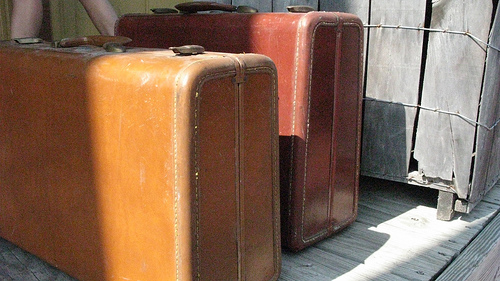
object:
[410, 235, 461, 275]
nails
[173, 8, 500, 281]
stitched seams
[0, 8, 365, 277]
suitcase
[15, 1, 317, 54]
apphendage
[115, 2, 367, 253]
suit case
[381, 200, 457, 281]
ground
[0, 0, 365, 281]
luggage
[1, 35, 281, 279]
brown suitcase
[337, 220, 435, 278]
wood decking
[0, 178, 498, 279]
floor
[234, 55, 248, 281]
seam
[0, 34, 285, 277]
briefcase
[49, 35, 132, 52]
handle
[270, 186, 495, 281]
slats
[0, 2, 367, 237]
box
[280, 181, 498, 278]
decking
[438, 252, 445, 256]
screws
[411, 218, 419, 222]
screws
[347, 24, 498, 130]
wire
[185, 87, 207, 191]
appointments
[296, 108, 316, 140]
appointments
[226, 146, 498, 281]
stand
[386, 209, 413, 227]
section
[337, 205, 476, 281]
sunlight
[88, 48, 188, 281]
sun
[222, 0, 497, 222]
crate